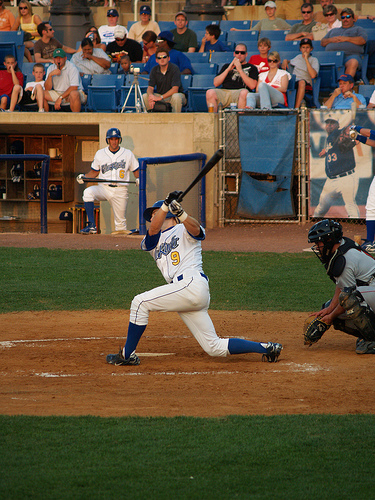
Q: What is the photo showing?
A: It is showing a field.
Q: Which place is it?
A: It is a field.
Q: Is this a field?
A: Yes, it is a field.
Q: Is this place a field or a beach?
A: It is a field.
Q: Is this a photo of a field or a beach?
A: It is showing a field.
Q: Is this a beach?
A: No, it is a field.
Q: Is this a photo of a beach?
A: No, the picture is showing a field.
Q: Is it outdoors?
A: Yes, it is outdoors.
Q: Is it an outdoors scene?
A: Yes, it is outdoors.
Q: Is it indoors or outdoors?
A: It is outdoors.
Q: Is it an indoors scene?
A: No, it is outdoors.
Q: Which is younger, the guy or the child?
A: The child is younger than the guy.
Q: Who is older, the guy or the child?
A: The guy is older than the child.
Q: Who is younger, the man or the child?
A: The child is younger than the man.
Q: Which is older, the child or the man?
A: The man is older than the child.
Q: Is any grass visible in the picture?
A: Yes, there is grass.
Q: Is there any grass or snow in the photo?
A: Yes, there is grass.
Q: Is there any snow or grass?
A: Yes, there is grass.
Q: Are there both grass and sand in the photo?
A: No, there is grass but no sand.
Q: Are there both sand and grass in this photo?
A: No, there is grass but no sand.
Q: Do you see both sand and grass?
A: No, there is grass but no sand.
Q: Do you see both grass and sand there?
A: No, there is grass but no sand.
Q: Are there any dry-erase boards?
A: No, there are no dry-erase boards.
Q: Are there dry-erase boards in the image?
A: No, there are no dry-erase boards.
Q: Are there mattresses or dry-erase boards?
A: No, there are no dry-erase boards or mattresses.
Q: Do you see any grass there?
A: Yes, there is grass.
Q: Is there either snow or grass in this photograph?
A: Yes, there is grass.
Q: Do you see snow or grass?
A: Yes, there is grass.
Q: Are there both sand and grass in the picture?
A: No, there is grass but no sand.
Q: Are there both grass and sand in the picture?
A: No, there is grass but no sand.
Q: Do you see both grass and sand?
A: No, there is grass but no sand.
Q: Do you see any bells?
A: No, there are no bells.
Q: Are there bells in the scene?
A: No, there are no bells.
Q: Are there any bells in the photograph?
A: No, there are no bells.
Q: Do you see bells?
A: No, there are no bells.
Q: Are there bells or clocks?
A: No, there are no bells or clocks.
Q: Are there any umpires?
A: No, there are no umpires.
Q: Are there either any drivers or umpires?
A: No, there are no umpires or drivers.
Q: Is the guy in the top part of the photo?
A: Yes, the guy is in the top of the image.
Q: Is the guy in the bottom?
A: No, the guy is in the top of the image.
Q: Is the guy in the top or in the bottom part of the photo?
A: The guy is in the top of the image.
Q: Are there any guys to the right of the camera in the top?
A: Yes, there is a guy to the right of the camera.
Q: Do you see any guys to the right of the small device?
A: Yes, there is a guy to the right of the camera.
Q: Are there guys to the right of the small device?
A: Yes, there is a guy to the right of the camera.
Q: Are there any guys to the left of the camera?
A: No, the guy is to the right of the camera.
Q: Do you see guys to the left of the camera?
A: No, the guy is to the right of the camera.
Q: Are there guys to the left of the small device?
A: No, the guy is to the right of the camera.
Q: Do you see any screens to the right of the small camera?
A: No, there is a guy to the right of the camera.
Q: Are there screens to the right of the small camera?
A: No, there is a guy to the right of the camera.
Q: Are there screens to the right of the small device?
A: No, there is a guy to the right of the camera.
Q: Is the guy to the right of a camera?
A: Yes, the guy is to the right of a camera.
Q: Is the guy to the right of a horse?
A: No, the guy is to the right of a camera.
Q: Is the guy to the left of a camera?
A: No, the guy is to the right of a camera.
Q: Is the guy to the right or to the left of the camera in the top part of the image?
A: The guy is to the right of the camera.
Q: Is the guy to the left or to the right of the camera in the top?
A: The guy is to the right of the camera.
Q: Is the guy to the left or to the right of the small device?
A: The guy is to the right of the camera.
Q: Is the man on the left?
A: Yes, the man is on the left of the image.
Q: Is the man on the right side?
A: No, the man is on the left of the image.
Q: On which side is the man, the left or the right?
A: The man is on the left of the image.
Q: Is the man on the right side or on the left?
A: The man is on the left of the image.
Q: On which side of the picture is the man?
A: The man is on the left of the image.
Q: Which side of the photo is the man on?
A: The man is on the left of the image.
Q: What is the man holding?
A: The man is holding the bat.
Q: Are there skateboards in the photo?
A: No, there are no skateboards.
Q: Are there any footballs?
A: No, there are no footballs.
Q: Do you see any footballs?
A: No, there are no footballs.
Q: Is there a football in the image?
A: No, there are no footballs.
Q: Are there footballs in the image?
A: No, there are no footballs.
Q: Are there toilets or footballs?
A: No, there are no footballs or toilets.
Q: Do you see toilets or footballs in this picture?
A: No, there are no footballs or toilets.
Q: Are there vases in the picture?
A: No, there are no vases.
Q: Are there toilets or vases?
A: No, there are no vases or toilets.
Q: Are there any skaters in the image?
A: No, there are no skaters.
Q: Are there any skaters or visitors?
A: No, there are no skaters or visitors.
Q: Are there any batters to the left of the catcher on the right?
A: Yes, there is a batter to the left of the catcher.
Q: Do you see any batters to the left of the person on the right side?
A: Yes, there is a batter to the left of the catcher.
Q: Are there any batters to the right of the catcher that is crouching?
A: No, the batter is to the left of the catcher.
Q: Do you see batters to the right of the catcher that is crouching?
A: No, the batter is to the left of the catcher.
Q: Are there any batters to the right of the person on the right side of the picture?
A: No, the batter is to the left of the catcher.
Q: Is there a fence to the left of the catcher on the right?
A: No, there is a batter to the left of the catcher.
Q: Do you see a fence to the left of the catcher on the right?
A: No, there is a batter to the left of the catcher.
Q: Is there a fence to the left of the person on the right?
A: No, there is a batter to the left of the catcher.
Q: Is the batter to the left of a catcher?
A: Yes, the batter is to the left of a catcher.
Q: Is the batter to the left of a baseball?
A: No, the batter is to the left of a catcher.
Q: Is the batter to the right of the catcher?
A: No, the batter is to the left of the catcher.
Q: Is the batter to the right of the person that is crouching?
A: No, the batter is to the left of the catcher.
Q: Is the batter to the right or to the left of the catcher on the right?
A: The batter is to the left of the catcher.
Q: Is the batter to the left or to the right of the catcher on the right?
A: The batter is to the left of the catcher.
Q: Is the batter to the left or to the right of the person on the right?
A: The batter is to the left of the catcher.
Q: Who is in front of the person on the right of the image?
A: The batter is in front of the catcher.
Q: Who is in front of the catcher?
A: The batter is in front of the catcher.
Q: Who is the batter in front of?
A: The batter is in front of the catcher.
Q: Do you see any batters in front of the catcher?
A: Yes, there is a batter in front of the catcher.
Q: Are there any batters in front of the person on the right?
A: Yes, there is a batter in front of the catcher.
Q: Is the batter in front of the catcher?
A: Yes, the batter is in front of the catcher.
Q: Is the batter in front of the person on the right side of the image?
A: Yes, the batter is in front of the catcher.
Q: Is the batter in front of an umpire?
A: No, the batter is in front of the catcher.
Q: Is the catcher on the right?
A: Yes, the catcher is on the right of the image.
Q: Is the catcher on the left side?
A: No, the catcher is on the right of the image.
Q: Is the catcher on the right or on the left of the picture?
A: The catcher is on the right of the image.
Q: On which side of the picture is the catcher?
A: The catcher is on the right of the image.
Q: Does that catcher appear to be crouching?
A: Yes, the catcher is crouching.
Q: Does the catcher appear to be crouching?
A: Yes, the catcher is crouching.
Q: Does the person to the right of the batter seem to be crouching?
A: Yes, the catcher is crouching.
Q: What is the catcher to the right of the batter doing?
A: The catcher is crouching.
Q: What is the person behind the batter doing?
A: The catcher is crouching.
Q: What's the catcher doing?
A: The catcher is crouching.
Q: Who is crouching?
A: The catcher is crouching.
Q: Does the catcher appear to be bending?
A: No, the catcher is crouching.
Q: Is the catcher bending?
A: No, the catcher is crouching.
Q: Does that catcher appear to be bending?
A: No, the catcher is crouching.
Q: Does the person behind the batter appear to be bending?
A: No, the catcher is crouching.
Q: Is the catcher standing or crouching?
A: The catcher is crouching.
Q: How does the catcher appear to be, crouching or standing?
A: The catcher is crouching.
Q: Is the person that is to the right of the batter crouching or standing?
A: The catcher is crouching.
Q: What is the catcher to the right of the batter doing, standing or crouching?
A: The catcher is crouching.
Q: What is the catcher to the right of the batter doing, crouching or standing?
A: The catcher is crouching.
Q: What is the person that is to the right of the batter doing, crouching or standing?
A: The catcher is crouching.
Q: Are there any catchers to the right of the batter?
A: Yes, there is a catcher to the right of the batter.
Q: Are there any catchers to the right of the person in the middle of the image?
A: Yes, there is a catcher to the right of the batter.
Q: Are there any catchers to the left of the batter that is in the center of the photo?
A: No, the catcher is to the right of the batter.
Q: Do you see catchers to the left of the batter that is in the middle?
A: No, the catcher is to the right of the batter.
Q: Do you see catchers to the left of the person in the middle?
A: No, the catcher is to the right of the batter.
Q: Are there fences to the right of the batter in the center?
A: No, there is a catcher to the right of the batter.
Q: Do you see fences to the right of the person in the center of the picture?
A: No, there is a catcher to the right of the batter.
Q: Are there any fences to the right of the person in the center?
A: No, there is a catcher to the right of the batter.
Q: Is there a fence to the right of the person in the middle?
A: No, there is a catcher to the right of the batter.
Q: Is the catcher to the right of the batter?
A: Yes, the catcher is to the right of the batter.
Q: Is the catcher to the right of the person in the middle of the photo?
A: Yes, the catcher is to the right of the batter.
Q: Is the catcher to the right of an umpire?
A: No, the catcher is to the right of the batter.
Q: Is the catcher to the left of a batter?
A: No, the catcher is to the right of a batter.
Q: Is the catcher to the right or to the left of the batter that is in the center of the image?
A: The catcher is to the right of the batter.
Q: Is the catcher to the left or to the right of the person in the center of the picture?
A: The catcher is to the right of the batter.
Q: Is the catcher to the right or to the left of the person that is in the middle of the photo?
A: The catcher is to the right of the batter.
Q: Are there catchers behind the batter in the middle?
A: Yes, there is a catcher behind the batter.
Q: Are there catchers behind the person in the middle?
A: Yes, there is a catcher behind the batter.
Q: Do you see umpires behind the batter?
A: No, there is a catcher behind the batter.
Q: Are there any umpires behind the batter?
A: No, there is a catcher behind the batter.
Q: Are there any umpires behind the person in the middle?
A: No, there is a catcher behind the batter.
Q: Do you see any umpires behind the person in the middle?
A: No, there is a catcher behind the batter.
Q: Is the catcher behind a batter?
A: Yes, the catcher is behind a batter.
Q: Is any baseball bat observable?
A: Yes, there is a baseball bat.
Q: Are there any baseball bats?
A: Yes, there is a baseball bat.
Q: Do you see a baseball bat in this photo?
A: Yes, there is a baseball bat.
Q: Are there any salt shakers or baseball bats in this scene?
A: Yes, there is a baseball bat.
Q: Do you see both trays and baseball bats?
A: No, there is a baseball bat but no trays.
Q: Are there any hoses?
A: No, there are no hoses.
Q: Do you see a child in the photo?
A: Yes, there is a child.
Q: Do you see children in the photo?
A: Yes, there is a child.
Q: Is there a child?
A: Yes, there is a child.